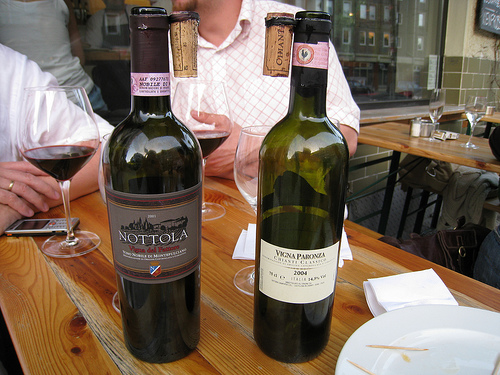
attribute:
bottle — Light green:
[250, 7, 354, 372]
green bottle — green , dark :
[251, 4, 358, 374]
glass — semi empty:
[11, 79, 109, 267]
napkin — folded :
[357, 265, 468, 312]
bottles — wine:
[102, 12, 349, 367]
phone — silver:
[17, 201, 74, 251]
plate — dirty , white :
[337, 299, 493, 369]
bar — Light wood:
[2, 194, 499, 374]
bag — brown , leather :
[433, 227, 482, 277]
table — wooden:
[1, 150, 496, 370]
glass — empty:
[231, 125, 267, 295]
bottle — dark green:
[93, 5, 213, 365]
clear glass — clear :
[16, 83, 101, 258]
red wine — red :
[18, 147, 99, 180]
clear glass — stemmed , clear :
[460, 90, 490, 150]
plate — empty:
[324, 298, 499, 373]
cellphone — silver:
[5, 212, 82, 238]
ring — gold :
[7, 175, 19, 189]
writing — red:
[109, 225, 200, 268]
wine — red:
[14, 122, 99, 192]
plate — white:
[319, 285, 498, 372]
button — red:
[47, 211, 61, 236]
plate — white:
[330, 305, 498, 369]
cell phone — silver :
[1, 206, 81, 240]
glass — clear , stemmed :
[422, 84, 449, 151]